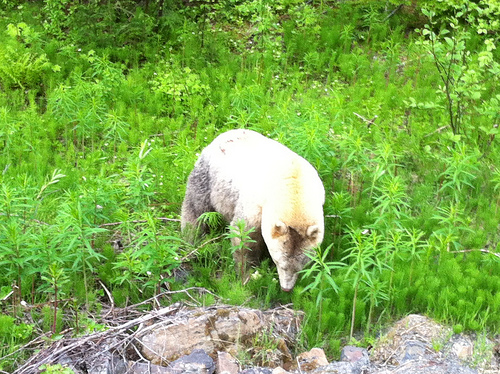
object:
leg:
[228, 211, 258, 283]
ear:
[302, 221, 319, 241]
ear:
[266, 215, 286, 237]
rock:
[77, 336, 144, 371]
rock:
[166, 341, 219, 371]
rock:
[364, 312, 492, 372]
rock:
[296, 336, 372, 371]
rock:
[250, 306, 304, 335]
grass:
[0, 0, 499, 347]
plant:
[418, 23, 487, 174]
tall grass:
[1, 52, 498, 339]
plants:
[0, 10, 494, 369]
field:
[17, 91, 177, 248]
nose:
[278, 285, 293, 293]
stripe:
[284, 155, 313, 232]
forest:
[0, 5, 495, 126]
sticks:
[90, 296, 197, 361]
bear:
[179, 128, 329, 293]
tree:
[420, 2, 499, 142]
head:
[258, 219, 324, 293]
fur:
[241, 150, 292, 192]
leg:
[162, 160, 216, 245]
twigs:
[32, 277, 67, 330]